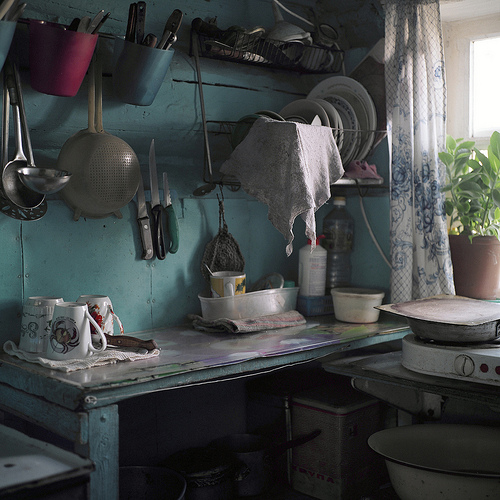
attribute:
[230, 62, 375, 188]
plates — close, white, round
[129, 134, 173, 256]
knifes — long, grey, black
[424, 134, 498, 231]
plant — green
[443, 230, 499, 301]
pot — round, brown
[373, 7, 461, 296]
curtain — white, blue